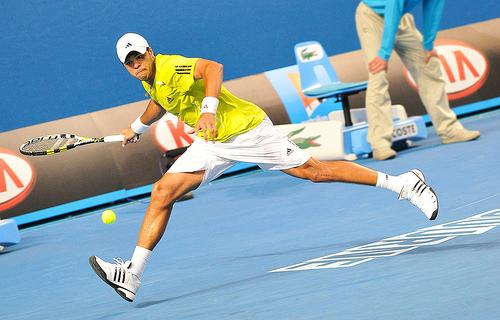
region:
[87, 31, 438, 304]
Man playing tennis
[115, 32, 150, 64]
Hat on the man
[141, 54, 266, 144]
Shirt on the man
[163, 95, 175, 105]
Brand logo on the man's shirt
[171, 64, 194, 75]
Stripes on the man's shirt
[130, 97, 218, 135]
Bracers on the man's wrists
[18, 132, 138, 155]
Racket in the man's hand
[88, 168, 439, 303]
Shoes on the man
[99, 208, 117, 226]
Tennis ball in the air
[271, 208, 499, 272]
Letters on the tennis court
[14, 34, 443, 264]
Tennis player swinging a tennis racket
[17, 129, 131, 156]
Black and white tennis racket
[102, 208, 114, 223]
Yellow tennis ball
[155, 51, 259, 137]
Bright yellow shirt with black striped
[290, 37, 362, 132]
Blue chair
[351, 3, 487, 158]
Person standing with hands on knees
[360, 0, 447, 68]
Person with a long sleeved blue shirt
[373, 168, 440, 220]
White socks and white shoes with black stripes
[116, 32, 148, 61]
White cap with black emblem on front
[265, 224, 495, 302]
Blue tennis court with white letters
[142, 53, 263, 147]
a yellow shirt on a tennis player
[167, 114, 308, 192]
white shorts on a tennis player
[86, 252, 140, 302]
a white and black tennis shoe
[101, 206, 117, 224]
a yellow tennis ball in the air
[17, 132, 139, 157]
a black, white, and yellow tennis racket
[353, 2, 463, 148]
tan pants on a man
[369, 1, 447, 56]
a blue shirt on a man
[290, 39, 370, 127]
a blue seat next to a tennis court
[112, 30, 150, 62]
a white cap on a man's head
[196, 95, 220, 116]
a white wristband on a man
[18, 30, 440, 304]
a man running to the side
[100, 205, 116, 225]
a bright green tennis ball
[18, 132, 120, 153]
a white, yellow, and black tennis racket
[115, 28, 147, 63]
a white tennis hat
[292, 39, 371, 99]
a blue plastic chair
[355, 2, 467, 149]
a pair of khaki jeans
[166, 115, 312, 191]
a pair of white tennis shorts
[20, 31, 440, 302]
a player swinging a tennis racket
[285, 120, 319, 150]
the lacoste logo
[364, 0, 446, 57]
a blue long sleeve garment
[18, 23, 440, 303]
a man wearing a yellow shirt playing tennis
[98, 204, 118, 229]
a tennis ball in the air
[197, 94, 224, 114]
a white wrist band on a wrist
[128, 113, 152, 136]
a white wrist band on a wrist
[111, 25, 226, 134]
a man wearing a white ball cap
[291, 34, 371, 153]
a blue chair on a tennis court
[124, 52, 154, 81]
the face of a man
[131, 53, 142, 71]
the nose of a man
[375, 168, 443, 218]
a white sock and white and black tennis shoe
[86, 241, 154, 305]
a white sock and white and black tennis shoe